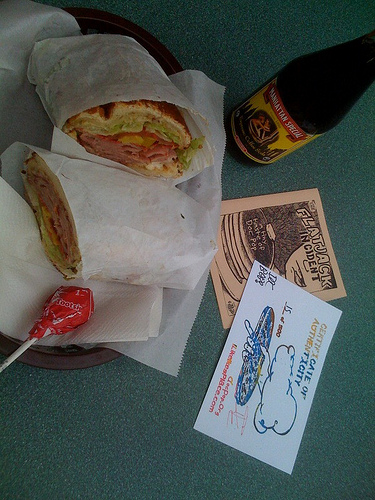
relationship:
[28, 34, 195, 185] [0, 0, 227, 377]
sahdwich wrapped in paper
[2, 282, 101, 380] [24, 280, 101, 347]
sucker wrapped in red paper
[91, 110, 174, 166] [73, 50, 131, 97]
sandwich wrapped in paper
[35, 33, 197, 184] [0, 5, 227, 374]
sandwich laying on napkin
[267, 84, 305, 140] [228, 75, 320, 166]
writing on label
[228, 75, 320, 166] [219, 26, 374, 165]
label on bottle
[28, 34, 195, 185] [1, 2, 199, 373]
sahdwich on brown plate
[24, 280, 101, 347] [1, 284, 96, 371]
red paper on sucker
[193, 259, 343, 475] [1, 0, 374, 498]
card on table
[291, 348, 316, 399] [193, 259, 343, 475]
writing on card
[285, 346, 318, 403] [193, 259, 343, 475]
letters on card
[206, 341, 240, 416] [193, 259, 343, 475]
letters on card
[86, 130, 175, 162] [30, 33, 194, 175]
ham on sandwich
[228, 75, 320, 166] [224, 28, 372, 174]
label on bottle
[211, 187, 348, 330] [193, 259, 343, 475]
orange card next to card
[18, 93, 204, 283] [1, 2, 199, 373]
sandwich on brown plate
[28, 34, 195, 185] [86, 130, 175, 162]
sahdwich with ham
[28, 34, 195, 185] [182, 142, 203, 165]
sahdwich with lettuce